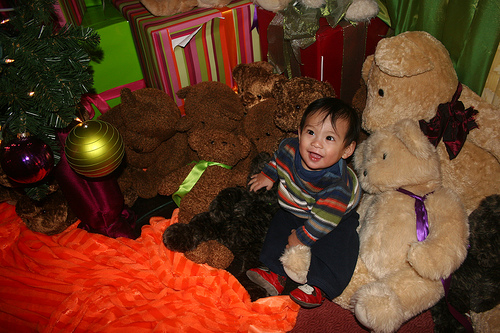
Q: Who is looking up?
A: The baby.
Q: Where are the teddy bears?
A: On the ground.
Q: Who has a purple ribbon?
A: The teddy bear on the bottom right.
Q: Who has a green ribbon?
A: The teddy bear to the child's right.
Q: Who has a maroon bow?
A: The largest teddy bear.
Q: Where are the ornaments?
A: On the Christmas tree.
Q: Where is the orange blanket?
A: In front of the teddy bears.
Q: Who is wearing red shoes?
A: The little boy.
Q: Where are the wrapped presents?
A: Behind the teddy bears.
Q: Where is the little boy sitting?
A: Next to the teddy bears.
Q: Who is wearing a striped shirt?
A: The little boy.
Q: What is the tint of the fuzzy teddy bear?
A: Beige.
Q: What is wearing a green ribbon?
A: Beige fuzzy teddy bear.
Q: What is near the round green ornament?
A: A round purple ornament.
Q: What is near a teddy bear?
A: A very small boy.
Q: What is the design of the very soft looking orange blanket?
A: Striped.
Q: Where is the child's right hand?
A: Resting on a dark teddy bear.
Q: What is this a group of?
A: Dark brown teddy bears.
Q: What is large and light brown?
A: Two bears.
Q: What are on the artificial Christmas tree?
A: Large round ornaments.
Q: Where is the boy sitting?
A: Among teddy bears.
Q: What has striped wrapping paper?
A: The present.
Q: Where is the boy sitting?
A: Near the teddy bears.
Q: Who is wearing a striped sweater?
A: The little boy.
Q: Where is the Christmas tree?
A: Next to the teddy bears.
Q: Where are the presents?
A: Behind the teddy bears.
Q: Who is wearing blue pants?
A: The little boy.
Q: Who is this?
A: A small child.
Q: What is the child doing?
A: Looking at the tree.